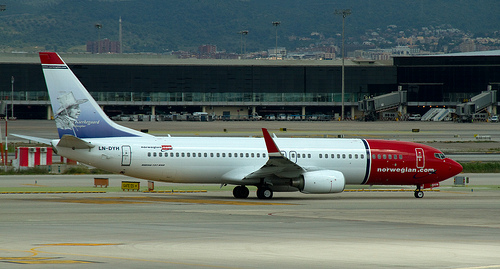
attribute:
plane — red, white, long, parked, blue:
[10, 51, 461, 196]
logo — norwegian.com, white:
[375, 164, 435, 175]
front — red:
[369, 140, 465, 187]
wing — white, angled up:
[244, 127, 307, 183]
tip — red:
[262, 126, 281, 153]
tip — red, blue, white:
[37, 52, 134, 139]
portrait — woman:
[52, 92, 91, 138]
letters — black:
[95, 144, 123, 152]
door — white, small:
[122, 143, 132, 169]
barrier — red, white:
[12, 146, 53, 167]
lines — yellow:
[56, 195, 294, 208]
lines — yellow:
[0, 238, 120, 268]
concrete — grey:
[0, 186, 496, 269]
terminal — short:
[0, 50, 498, 119]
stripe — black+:
[362, 138, 372, 185]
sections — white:
[52, 135, 365, 183]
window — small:
[155, 152, 159, 159]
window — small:
[158, 152, 165, 158]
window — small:
[164, 152, 170, 159]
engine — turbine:
[292, 169, 345, 197]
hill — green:
[2, 3, 498, 53]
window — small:
[149, 152, 153, 160]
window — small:
[175, 152, 180, 159]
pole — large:
[337, 11, 353, 120]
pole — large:
[272, 19, 285, 58]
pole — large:
[238, 28, 252, 58]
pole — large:
[114, 14, 124, 57]